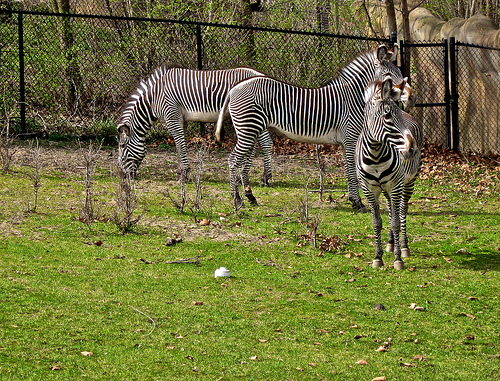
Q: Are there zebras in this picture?
A: Yes, there is a zebra.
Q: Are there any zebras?
A: Yes, there is a zebra.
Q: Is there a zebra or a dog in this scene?
A: Yes, there is a zebra.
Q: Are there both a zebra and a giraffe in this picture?
A: No, there is a zebra but no giraffes.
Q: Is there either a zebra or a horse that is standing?
A: Yes, the zebra is standing.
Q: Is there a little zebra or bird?
A: Yes, there is a little zebra.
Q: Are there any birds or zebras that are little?
A: Yes, the zebra is little.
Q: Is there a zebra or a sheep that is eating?
A: Yes, the zebra is eating.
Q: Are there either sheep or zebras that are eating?
A: Yes, the zebra is eating.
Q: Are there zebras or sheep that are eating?
A: Yes, the zebra is eating.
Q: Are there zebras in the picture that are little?
A: Yes, there is a little zebra.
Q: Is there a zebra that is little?
A: Yes, there is a zebra that is little.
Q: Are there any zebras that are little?
A: Yes, there is a zebra that is little.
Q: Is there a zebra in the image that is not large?
A: Yes, there is a little zebra.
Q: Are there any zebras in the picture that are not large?
A: Yes, there is a little zebra.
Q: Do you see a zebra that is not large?
A: Yes, there is a little zebra.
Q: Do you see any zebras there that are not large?
A: Yes, there is a little zebra.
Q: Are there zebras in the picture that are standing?
A: Yes, there is a zebra that is standing.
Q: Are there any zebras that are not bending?
A: Yes, there is a zebra that is standing.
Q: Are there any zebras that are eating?
A: Yes, there is a zebra that is eating.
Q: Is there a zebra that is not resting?
A: Yes, there is a zebra that is eating.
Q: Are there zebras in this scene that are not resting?
A: Yes, there is a zebra that is eating.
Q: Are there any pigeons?
A: No, there are no pigeons.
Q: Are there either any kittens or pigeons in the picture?
A: No, there are no pigeons or kittens.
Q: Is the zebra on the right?
A: Yes, the zebra is on the right of the image.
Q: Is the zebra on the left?
A: No, the zebra is on the right of the image.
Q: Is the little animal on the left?
A: No, the zebra is on the right of the image.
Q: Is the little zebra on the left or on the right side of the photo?
A: The zebra is on the right of the image.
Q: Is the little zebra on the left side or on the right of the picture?
A: The zebra is on the right of the image.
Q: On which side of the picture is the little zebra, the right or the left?
A: The zebra is on the right of the image.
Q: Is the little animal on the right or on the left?
A: The zebra is on the right of the image.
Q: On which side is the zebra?
A: The zebra is on the right of the image.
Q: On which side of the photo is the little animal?
A: The zebra is on the right of the image.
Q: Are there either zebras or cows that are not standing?
A: No, there is a zebra but it is standing.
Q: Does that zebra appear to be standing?
A: Yes, the zebra is standing.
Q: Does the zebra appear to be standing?
A: Yes, the zebra is standing.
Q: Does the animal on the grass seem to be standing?
A: Yes, the zebra is standing.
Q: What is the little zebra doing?
A: The zebra is standing.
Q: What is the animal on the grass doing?
A: The zebra is standing.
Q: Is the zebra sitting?
A: No, the zebra is standing.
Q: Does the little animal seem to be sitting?
A: No, the zebra is standing.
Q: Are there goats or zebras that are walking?
A: No, there is a zebra but it is standing.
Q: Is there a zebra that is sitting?
A: No, there is a zebra but it is standing.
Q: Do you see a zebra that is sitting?
A: No, there is a zebra but it is standing.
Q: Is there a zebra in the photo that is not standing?
A: No, there is a zebra but it is standing.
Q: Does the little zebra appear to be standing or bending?
A: The zebra is standing.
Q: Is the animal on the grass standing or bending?
A: The zebra is standing.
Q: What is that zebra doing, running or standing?
A: The zebra is standing.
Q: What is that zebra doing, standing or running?
A: The zebra is standing.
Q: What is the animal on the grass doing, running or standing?
A: The zebra is standing.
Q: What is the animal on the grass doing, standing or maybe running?
A: The zebra is standing.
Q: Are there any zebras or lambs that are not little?
A: No, there is a zebra but it is little.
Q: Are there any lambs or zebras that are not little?
A: No, there is a zebra but it is little.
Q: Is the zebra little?
A: Yes, the zebra is little.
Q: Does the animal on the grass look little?
A: Yes, the zebra is little.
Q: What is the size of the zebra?
A: The zebra is little.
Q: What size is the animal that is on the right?
A: The zebra is little.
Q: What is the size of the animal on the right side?
A: The zebra is little.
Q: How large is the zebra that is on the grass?
A: The zebra is little.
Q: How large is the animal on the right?
A: The zebra is little.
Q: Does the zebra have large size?
A: No, the zebra is little.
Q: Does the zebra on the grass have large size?
A: No, the zebra is little.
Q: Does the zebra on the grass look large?
A: No, the zebra is little.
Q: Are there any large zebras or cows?
A: No, there is a zebra but it is little.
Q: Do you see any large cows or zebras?
A: No, there is a zebra but it is little.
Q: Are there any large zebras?
A: No, there is a zebra but it is little.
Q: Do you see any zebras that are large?
A: No, there is a zebra but it is little.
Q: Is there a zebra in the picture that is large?
A: No, there is a zebra but it is little.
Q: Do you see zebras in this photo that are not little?
A: No, there is a zebra but it is little.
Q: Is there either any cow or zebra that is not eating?
A: No, there is a zebra but it is eating.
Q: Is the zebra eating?
A: Yes, the zebra is eating.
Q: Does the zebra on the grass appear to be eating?
A: Yes, the zebra is eating.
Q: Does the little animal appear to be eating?
A: Yes, the zebra is eating.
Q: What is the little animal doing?
A: The zebra is eating.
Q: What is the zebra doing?
A: The zebra is eating.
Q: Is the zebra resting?
A: No, the zebra is eating.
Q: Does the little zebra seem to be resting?
A: No, the zebra is eating.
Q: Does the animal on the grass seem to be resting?
A: No, the zebra is eating.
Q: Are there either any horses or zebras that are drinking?
A: No, there is a zebra but it is eating.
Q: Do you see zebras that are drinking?
A: No, there is a zebra but it is eating.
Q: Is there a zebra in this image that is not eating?
A: No, there is a zebra but it is eating.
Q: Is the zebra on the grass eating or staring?
A: The zebra is eating.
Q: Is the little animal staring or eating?
A: The zebra is eating.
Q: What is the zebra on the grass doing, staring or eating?
A: The zebra is eating.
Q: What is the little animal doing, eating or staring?
A: The zebra is eating.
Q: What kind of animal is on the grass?
A: The animal is a zebra.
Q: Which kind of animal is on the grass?
A: The animal is a zebra.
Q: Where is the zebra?
A: The zebra is on the grass.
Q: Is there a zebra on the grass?
A: Yes, there is a zebra on the grass.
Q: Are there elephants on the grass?
A: No, there is a zebra on the grass.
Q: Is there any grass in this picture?
A: Yes, there is grass.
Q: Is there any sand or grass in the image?
A: Yes, there is grass.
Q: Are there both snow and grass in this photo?
A: No, there is grass but no snow.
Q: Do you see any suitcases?
A: No, there are no suitcases.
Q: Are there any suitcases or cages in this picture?
A: No, there are no suitcases or cages.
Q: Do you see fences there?
A: Yes, there is a fence.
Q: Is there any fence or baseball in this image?
A: Yes, there is a fence.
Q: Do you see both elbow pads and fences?
A: No, there is a fence but no elbow pads.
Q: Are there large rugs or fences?
A: Yes, there is a large fence.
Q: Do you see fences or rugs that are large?
A: Yes, the fence is large.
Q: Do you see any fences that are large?
A: Yes, there is a large fence.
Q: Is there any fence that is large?
A: Yes, there is a fence that is large.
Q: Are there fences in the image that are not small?
A: Yes, there is a large fence.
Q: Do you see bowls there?
A: No, there are no bowls.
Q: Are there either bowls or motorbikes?
A: No, there are no bowls or motorbikes.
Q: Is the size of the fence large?
A: Yes, the fence is large.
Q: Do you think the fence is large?
A: Yes, the fence is large.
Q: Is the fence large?
A: Yes, the fence is large.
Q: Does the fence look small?
A: No, the fence is large.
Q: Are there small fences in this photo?
A: No, there is a fence but it is large.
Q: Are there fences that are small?
A: No, there is a fence but it is large.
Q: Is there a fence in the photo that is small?
A: No, there is a fence but it is large.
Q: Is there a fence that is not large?
A: No, there is a fence but it is large.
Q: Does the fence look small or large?
A: The fence is large.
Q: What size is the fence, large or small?
A: The fence is large.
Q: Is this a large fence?
A: Yes, this is a large fence.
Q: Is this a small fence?
A: No, this is a large fence.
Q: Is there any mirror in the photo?
A: No, there are no mirrors.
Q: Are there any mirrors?
A: No, there are no mirrors.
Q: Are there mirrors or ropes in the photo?
A: No, there are no mirrors or ropes.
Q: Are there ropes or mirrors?
A: No, there are no mirrors or ropes.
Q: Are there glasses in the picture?
A: No, there are no glasses.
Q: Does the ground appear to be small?
A: Yes, the ground is small.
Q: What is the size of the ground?
A: The ground is small.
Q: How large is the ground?
A: The ground is small.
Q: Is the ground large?
A: No, the ground is small.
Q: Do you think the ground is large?
A: No, the ground is small.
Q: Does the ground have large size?
A: No, the ground is small.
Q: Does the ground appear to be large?
A: No, the ground is small.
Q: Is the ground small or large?
A: The ground is small.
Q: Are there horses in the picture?
A: No, there are no horses.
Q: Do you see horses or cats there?
A: No, there are no horses or cats.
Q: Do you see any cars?
A: No, there are no cars.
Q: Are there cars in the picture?
A: No, there are no cars.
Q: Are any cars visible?
A: No, there are no cars.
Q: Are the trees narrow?
A: Yes, the trees are narrow.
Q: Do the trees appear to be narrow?
A: Yes, the trees are narrow.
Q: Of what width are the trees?
A: The trees are narrow.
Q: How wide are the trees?
A: The trees are narrow.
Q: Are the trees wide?
A: No, the trees are narrow.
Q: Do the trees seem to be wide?
A: No, the trees are narrow.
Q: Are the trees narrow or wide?
A: The trees are narrow.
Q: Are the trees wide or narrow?
A: The trees are narrow.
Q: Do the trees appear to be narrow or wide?
A: The trees are narrow.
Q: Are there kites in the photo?
A: No, there are no kites.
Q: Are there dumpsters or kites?
A: No, there are no kites or dumpsters.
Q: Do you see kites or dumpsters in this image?
A: No, there are no kites or dumpsters.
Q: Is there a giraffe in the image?
A: No, there are no giraffes.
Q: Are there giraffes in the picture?
A: No, there are no giraffes.